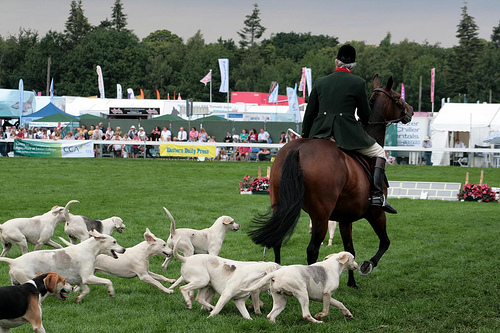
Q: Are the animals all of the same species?
A: No, there are both horses and dogs.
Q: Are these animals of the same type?
A: No, there are both horses and dogs.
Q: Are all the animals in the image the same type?
A: No, they are horses and dogs.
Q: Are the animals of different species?
A: Yes, they are horses and dogs.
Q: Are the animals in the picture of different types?
A: Yes, they are horses and dogs.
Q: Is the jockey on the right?
A: Yes, the jockey is on the right of the image.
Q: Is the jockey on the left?
A: No, the jockey is on the right of the image.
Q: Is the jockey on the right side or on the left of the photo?
A: The jockey is on the right of the image.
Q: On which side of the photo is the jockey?
A: The jockey is on the right of the image.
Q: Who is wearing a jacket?
A: The jockey is wearing a jacket.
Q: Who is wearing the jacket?
A: The jockey is wearing a jacket.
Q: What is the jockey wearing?
A: The jockey is wearing a jacket.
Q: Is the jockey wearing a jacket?
A: Yes, the jockey is wearing a jacket.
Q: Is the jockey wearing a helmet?
A: No, the jockey is wearing a jacket.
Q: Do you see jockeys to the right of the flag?
A: Yes, there is a jockey to the right of the flag.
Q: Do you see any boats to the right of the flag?
A: No, there is a jockey to the right of the flag.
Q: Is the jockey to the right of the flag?
A: Yes, the jockey is to the right of the flag.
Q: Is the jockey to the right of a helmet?
A: No, the jockey is to the right of the flag.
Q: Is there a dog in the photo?
A: Yes, there is a dog.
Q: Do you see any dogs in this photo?
A: Yes, there is a dog.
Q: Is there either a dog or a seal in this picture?
A: Yes, there is a dog.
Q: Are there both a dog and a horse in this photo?
A: Yes, there are both a dog and a horse.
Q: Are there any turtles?
A: No, there are no turtles.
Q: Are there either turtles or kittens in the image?
A: No, there are no turtles or kittens.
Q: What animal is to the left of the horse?
A: The animal is a dog.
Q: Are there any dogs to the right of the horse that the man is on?
A: No, the dog is to the left of the horse.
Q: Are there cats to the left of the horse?
A: No, there is a dog to the left of the horse.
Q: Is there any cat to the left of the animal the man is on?
A: No, there is a dog to the left of the horse.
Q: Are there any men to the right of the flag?
A: Yes, there is a man to the right of the flag.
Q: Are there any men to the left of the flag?
A: No, the man is to the right of the flag.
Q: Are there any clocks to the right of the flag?
A: No, there is a man to the right of the flag.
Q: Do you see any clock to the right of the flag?
A: No, there is a man to the right of the flag.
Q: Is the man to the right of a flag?
A: Yes, the man is to the right of a flag.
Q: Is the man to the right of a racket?
A: No, the man is to the right of a flag.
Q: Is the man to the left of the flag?
A: No, the man is to the right of the flag.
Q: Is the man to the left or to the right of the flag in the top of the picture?
A: The man is to the right of the flag.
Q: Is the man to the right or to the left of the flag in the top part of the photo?
A: The man is to the right of the flag.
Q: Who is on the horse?
A: The man is on the horse.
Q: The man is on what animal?
A: The man is on the horse.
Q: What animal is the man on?
A: The man is on the horse.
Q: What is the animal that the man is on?
A: The animal is a horse.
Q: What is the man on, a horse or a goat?
A: The man is on a horse.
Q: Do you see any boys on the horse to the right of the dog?
A: No, there is a man on the horse.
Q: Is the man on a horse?
A: Yes, the man is on a horse.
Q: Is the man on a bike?
A: No, the man is on a horse.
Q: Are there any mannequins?
A: No, there are no mannequins.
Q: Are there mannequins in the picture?
A: No, there are no mannequins.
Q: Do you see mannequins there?
A: No, there are no mannequins.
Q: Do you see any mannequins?
A: No, there are no mannequins.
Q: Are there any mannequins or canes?
A: No, there are no mannequins or canes.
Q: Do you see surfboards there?
A: No, there are no surfboards.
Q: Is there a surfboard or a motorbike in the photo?
A: No, there are no surfboards or motorcycles.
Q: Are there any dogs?
A: Yes, there is a dog.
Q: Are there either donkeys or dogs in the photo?
A: Yes, there is a dog.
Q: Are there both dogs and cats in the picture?
A: No, there is a dog but no cats.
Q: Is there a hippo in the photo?
A: No, there are no hippos.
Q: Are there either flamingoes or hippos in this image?
A: No, there are no hippos or flamingoes.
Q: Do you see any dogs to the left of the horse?
A: Yes, there is a dog to the left of the horse.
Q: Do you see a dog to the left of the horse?
A: Yes, there is a dog to the left of the horse.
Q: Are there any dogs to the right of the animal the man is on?
A: No, the dog is to the left of the horse.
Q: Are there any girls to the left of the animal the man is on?
A: No, there is a dog to the left of the horse.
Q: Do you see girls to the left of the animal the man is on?
A: No, there is a dog to the left of the horse.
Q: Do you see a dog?
A: Yes, there is a dog.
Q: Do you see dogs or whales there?
A: Yes, there is a dog.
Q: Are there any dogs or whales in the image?
A: Yes, there is a dog.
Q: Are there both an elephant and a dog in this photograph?
A: No, there is a dog but no elephants.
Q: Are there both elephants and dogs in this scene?
A: No, there is a dog but no elephants.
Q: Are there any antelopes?
A: No, there are no antelopes.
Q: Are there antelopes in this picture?
A: No, there are no antelopes.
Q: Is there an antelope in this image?
A: No, there are no antelopes.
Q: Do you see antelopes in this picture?
A: No, there are no antelopes.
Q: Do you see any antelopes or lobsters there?
A: No, there are no antelopes or lobsters.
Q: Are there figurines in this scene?
A: No, there are no figurines.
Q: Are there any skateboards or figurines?
A: No, there are no figurines or skateboards.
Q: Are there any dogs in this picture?
A: Yes, there is a dog.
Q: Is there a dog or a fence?
A: Yes, there is a dog.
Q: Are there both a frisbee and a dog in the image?
A: No, there is a dog but no frisbees.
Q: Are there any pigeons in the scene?
A: No, there are no pigeons.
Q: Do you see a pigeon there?
A: No, there are no pigeons.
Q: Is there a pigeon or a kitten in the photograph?
A: No, there are no pigeons or kittens.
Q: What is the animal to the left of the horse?
A: The animal is a dog.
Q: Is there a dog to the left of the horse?
A: Yes, there is a dog to the left of the horse.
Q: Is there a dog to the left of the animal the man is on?
A: Yes, there is a dog to the left of the horse.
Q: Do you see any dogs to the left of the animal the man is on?
A: Yes, there is a dog to the left of the horse.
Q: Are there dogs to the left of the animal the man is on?
A: Yes, there is a dog to the left of the horse.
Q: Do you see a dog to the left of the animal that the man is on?
A: Yes, there is a dog to the left of the horse.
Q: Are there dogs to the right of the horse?
A: No, the dog is to the left of the horse.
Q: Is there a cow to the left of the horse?
A: No, there is a dog to the left of the horse.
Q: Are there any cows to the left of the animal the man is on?
A: No, there is a dog to the left of the horse.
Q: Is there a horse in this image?
A: Yes, there is a horse.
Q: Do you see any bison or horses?
A: Yes, there is a horse.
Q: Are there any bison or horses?
A: Yes, there is a horse.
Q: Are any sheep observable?
A: No, there are no sheep.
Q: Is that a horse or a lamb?
A: That is a horse.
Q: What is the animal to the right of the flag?
A: The animal is a horse.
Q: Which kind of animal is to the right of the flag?
A: The animal is a horse.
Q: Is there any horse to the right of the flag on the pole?
A: Yes, there is a horse to the right of the flag.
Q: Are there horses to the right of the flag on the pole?
A: Yes, there is a horse to the right of the flag.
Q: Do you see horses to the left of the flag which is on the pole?
A: No, the horse is to the right of the flag.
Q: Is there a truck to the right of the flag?
A: No, there is a horse to the right of the flag.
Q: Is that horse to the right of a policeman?
A: No, the horse is to the right of the flag.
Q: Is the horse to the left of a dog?
A: No, the horse is to the right of a dog.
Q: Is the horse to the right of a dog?
A: Yes, the horse is to the right of a dog.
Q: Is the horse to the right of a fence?
A: No, the horse is to the right of a dog.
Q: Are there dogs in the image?
A: Yes, there is a dog.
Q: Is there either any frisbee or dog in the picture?
A: Yes, there is a dog.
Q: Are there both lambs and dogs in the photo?
A: No, there is a dog but no lambs.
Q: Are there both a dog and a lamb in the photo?
A: No, there is a dog but no lambs.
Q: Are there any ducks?
A: No, there are no ducks.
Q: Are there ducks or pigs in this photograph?
A: No, there are no ducks or pigs.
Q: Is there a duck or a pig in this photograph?
A: No, there are no ducks or pigs.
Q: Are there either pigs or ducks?
A: No, there are no ducks or pigs.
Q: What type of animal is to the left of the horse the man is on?
A: The animal is a dog.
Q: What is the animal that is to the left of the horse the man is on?
A: The animal is a dog.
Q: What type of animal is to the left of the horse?
A: The animal is a dog.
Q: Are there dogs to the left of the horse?
A: Yes, there is a dog to the left of the horse.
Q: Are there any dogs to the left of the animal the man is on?
A: Yes, there is a dog to the left of the horse.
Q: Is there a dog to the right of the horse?
A: No, the dog is to the left of the horse.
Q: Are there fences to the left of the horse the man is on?
A: No, there is a dog to the left of the horse.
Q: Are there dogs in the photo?
A: Yes, there is a dog.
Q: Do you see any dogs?
A: Yes, there is a dog.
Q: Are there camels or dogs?
A: Yes, there is a dog.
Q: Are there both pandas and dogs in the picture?
A: No, there is a dog but no pandas.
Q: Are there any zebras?
A: No, there are no zebras.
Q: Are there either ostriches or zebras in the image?
A: No, there are no zebras or ostriches.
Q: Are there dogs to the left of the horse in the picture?
A: Yes, there is a dog to the left of the horse.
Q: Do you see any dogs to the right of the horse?
A: No, the dog is to the left of the horse.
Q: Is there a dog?
A: Yes, there is a dog.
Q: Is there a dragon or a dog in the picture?
A: Yes, there is a dog.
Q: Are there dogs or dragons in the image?
A: Yes, there is a dog.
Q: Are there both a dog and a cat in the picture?
A: No, there is a dog but no cats.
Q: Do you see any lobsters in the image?
A: No, there are no lobsters.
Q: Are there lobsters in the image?
A: No, there are no lobsters.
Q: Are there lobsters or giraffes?
A: No, there are no lobsters or giraffes.